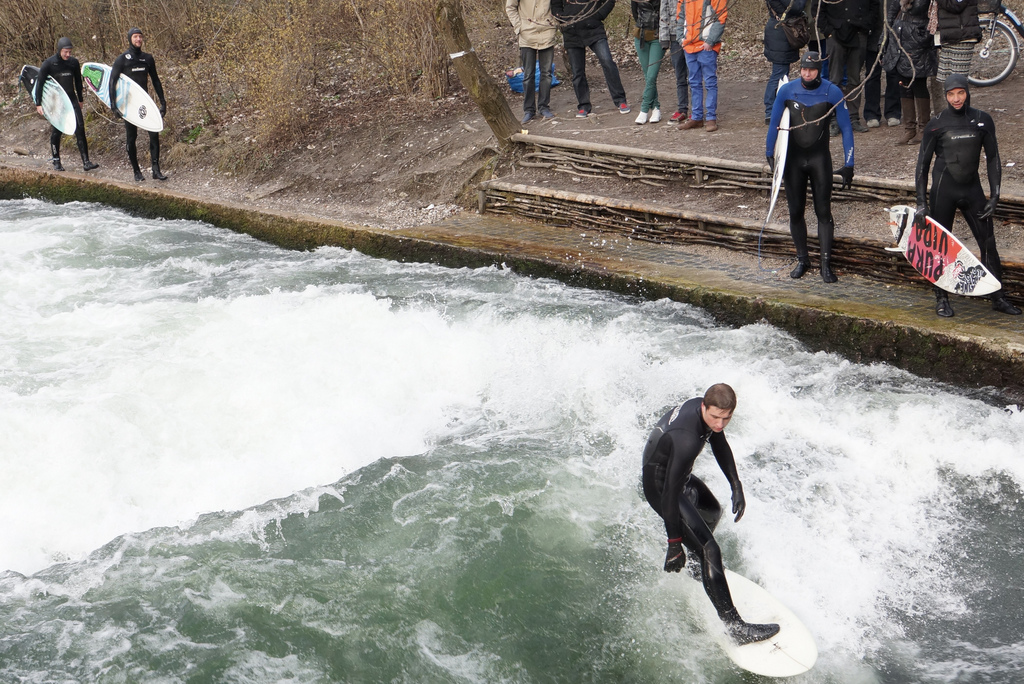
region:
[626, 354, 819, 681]
a man on a surfboard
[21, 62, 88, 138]
a white and black surfboard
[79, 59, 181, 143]
a white green and black surfboard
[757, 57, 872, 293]
a blue and black wetsuit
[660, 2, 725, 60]
an orange and gray jacket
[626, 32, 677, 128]
green pants and white shoes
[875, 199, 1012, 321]
a white black and red surfboard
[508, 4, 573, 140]
tan jacket and black pants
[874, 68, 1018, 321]
man in black wet suit holding surfboard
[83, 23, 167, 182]
man in black wet suit walking with surfboard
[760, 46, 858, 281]
man in blue and black wetsuit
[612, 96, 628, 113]
black shoe with red laces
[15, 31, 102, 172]
man in black wet suit walking with surfboard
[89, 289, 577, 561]
white waves on water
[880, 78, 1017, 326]
man holding surfboard with right hand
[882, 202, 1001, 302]
red and white surfboard with black lettering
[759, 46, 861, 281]
man wearing blue and black wet suit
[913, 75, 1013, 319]
man wearing black wet suit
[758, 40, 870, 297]
A person is standing up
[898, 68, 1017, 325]
A person is standing up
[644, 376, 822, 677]
the surfer is riding a wave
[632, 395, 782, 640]
the man is wearing a wetsuit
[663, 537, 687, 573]
the man is wearing gloves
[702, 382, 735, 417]
the man's hair is wet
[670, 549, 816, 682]
the surfboard is white in color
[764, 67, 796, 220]
the man is holding a surfboard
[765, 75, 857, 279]
the man is wearing a black and blue wetsuit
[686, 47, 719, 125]
the man is wearing jeans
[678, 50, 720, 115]
the jeans are blue in color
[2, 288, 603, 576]
a wave is moving forward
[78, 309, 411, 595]
white waves on water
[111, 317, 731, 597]
water is dark green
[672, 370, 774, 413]
man has brown hair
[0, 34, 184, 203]
two people standing on shore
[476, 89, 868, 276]
three steps on shore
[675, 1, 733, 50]
person has orange coat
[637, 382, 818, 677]
the man is standing on a surfboard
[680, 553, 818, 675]
the surfboard is white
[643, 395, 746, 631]
the wetsuit is black